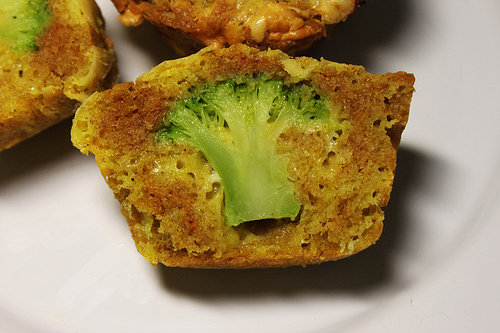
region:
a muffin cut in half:
[66, 4, 483, 314]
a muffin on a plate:
[104, 46, 472, 329]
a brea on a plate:
[129, 44, 406, 319]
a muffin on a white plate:
[118, 46, 497, 320]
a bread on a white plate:
[54, 40, 492, 331]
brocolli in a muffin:
[74, 6, 446, 299]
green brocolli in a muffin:
[124, 56, 439, 271]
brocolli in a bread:
[97, 21, 424, 267]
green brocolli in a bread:
[169, 24, 408, 306]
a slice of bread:
[54, 26, 372, 270]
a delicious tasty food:
[97, 47, 477, 267]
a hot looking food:
[73, 63, 458, 303]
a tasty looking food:
[82, 68, 414, 285]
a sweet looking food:
[55, 15, 498, 308]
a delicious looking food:
[47, 2, 484, 289]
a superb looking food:
[83, 56, 493, 305]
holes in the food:
[302, 125, 344, 159]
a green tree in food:
[154, 56, 341, 214]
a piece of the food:
[18, 17, 493, 282]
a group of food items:
[5, 8, 453, 291]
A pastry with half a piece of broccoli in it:
[65, 43, 416, 271]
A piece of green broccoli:
[157, 72, 337, 231]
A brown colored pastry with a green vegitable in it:
[68, 41, 413, 267]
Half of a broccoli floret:
[157, 74, 332, 226]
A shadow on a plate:
[155, 262, 410, 303]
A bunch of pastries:
[0, 0, 422, 272]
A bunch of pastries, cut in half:
[0, 0, 422, 269]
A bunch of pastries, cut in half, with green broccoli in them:
[0, 0, 416, 267]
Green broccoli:
[0, 0, 53, 55]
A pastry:
[0, 0, 122, 154]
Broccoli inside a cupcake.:
[147, 62, 372, 253]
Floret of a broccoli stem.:
[161, 92, 223, 152]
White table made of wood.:
[413, 190, 473, 331]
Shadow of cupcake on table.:
[415, 145, 465, 307]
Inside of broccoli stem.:
[247, 133, 277, 213]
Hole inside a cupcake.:
[112, 180, 138, 211]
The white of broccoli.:
[233, 138, 288, 234]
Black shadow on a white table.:
[398, 135, 433, 271]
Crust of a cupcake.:
[169, 3, 331, 44]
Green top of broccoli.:
[171, 76, 254, 118]